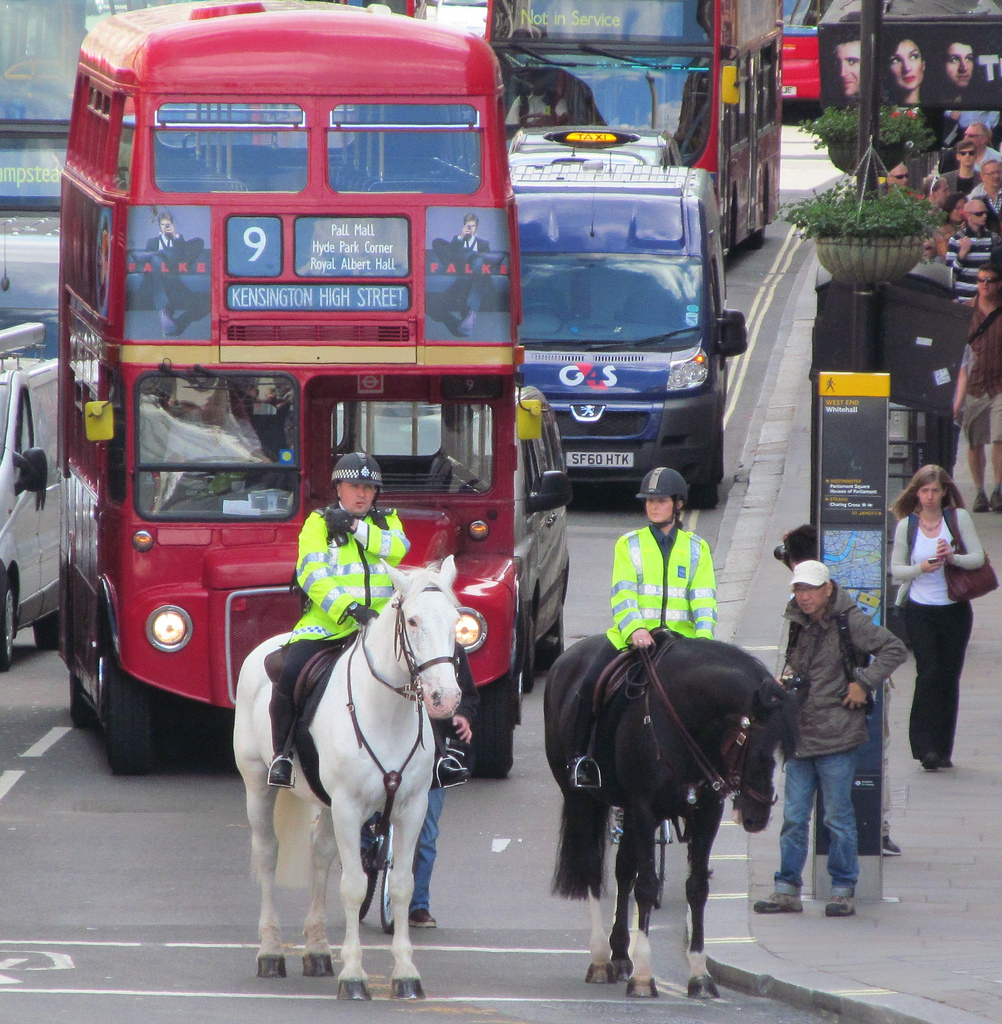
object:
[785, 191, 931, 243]
plant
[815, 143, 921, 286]
basket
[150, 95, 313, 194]
window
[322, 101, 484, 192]
window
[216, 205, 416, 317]
sign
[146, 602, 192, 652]
headlight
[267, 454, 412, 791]
man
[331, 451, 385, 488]
helmet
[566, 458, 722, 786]
woman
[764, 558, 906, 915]
man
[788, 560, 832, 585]
hat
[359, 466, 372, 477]
department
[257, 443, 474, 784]
police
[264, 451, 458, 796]
officers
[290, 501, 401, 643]
vests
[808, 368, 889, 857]
posts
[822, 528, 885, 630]
maps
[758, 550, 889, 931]
visitors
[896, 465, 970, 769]
commuters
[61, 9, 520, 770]
automobiles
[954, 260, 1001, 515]
people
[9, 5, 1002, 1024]
city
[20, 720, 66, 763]
lines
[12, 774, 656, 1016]
road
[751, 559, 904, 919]
pedestrians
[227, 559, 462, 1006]
horse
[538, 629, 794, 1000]
horse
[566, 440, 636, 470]
plate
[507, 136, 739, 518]
car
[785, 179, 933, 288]
pot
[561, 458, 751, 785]
person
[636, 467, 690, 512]
helmet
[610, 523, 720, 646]
coat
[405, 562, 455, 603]
mane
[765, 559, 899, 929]
person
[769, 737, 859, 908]
jeans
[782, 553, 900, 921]
man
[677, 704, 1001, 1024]
corner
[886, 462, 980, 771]
woman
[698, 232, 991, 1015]
sidewalk